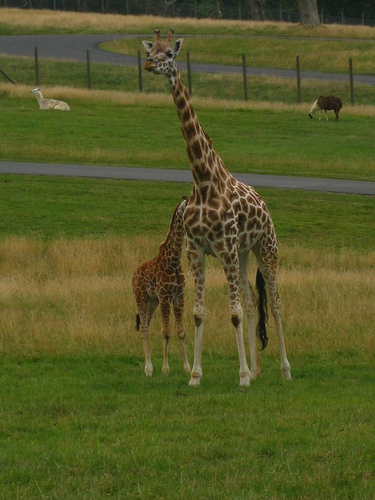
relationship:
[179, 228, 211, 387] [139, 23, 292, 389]
front leg of adult giraffe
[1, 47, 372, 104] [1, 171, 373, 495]
fence along grass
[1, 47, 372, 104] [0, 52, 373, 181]
fence along grass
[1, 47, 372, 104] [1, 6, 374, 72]
fence along grass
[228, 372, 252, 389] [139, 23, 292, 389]
hoof of adult giraffe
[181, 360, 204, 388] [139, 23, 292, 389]
hoof of adult giraffe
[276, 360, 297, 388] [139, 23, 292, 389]
hoof of adult giraffe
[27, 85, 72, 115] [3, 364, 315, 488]
llama in grass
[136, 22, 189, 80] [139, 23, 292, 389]
head of adult giraffe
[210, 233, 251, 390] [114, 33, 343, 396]
front leg of giraffe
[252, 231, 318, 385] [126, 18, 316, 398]
leg of giraffe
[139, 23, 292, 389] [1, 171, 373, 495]
adult giraffe standing on grass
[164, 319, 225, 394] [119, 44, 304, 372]
leg of giraffe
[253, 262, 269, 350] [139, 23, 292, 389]
tail of adult giraffe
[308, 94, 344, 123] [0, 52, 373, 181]
llama grazing on grass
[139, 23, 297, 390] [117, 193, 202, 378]
adult giraffe with baby giraffe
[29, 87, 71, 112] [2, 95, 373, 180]
llama laying on grass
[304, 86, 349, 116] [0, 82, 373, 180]
llama eating grass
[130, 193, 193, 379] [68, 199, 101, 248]
baby giraffe standing on grass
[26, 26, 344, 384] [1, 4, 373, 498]
animals in field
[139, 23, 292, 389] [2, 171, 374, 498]
adult giraffe in field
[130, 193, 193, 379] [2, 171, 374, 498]
baby giraffe in field